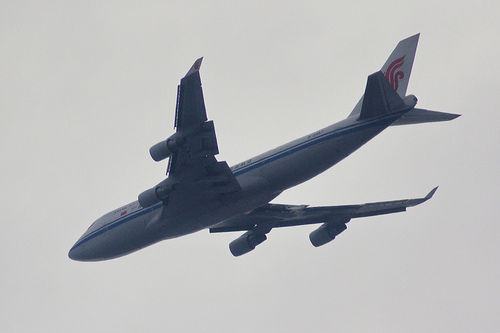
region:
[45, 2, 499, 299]
airplane flying in the air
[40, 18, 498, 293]
airplane flying in the air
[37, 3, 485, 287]
airplane flying in the air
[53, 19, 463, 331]
airplane flying in the air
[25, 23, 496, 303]
airplane flying in the air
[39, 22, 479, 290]
airplane flying in the air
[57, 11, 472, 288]
airplane flying in the air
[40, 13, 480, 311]
airplane flying in the air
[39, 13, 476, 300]
airplane flying in the air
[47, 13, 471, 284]
airplane flying in the air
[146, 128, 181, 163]
this is an aeroplane engine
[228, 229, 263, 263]
this is an aeroplane engine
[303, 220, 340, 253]
this is an aeroplane engine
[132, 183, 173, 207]
this is an aeroplane engine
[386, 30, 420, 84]
this is a rudder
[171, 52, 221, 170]
this is a wing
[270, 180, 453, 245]
this is a wing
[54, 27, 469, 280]
Plane in the air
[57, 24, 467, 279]
Plane is in the air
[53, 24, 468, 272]
Airplane in the air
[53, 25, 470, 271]
Airplane is in the air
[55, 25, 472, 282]
Plane is flying in the air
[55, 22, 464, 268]
Airplane flying in the air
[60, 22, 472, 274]
Airplane is flying in the air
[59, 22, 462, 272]
Plane is up in the air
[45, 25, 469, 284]
Airplane is up in the air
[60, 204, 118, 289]
front of a plane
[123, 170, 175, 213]
turbine of a plane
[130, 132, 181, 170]
turbine of a plane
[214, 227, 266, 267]
turbine of a plane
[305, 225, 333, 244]
turbine of a plane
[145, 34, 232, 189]
wing of a plane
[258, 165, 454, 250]
wing of a plane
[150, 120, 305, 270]
body of a plane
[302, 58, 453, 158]
tail of a plane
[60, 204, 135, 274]
front of a plane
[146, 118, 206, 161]
turbine of a plane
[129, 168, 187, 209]
turbine of a plane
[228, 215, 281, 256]
turbine of a plane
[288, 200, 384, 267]
turbine of a plane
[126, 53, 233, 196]
wing of a plane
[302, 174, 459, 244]
wing of a plane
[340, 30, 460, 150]
tail of a plane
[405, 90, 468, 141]
wing of a plane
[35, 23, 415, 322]
a plane in the air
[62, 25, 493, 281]
a plane in the air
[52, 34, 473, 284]
gray airplane in the sky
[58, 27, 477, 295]
gray airplane in the cloudy sky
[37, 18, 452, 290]
gray airplane in the sky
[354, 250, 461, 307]
white clouds in the sky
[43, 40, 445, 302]
gray airplane in the sky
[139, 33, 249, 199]
wing on the gray airplane in the sky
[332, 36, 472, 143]
tail on the gray airplane in the sky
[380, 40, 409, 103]
red symbol on back of plane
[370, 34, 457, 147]
white plane tail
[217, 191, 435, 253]
white plane wing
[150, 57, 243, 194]
white plane wing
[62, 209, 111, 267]
white front of plane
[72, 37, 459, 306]
white plane flying in sky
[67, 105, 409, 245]
blue stripe on white plane